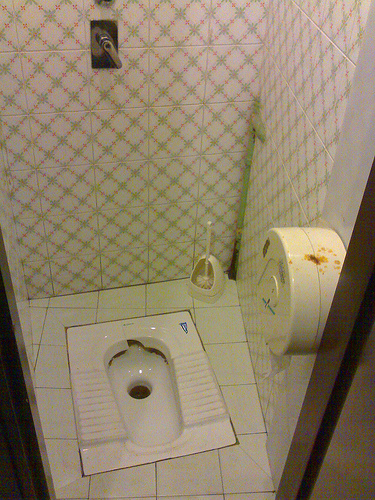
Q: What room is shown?
A: It is a bathroom.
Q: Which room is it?
A: It is a bathroom.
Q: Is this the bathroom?
A: Yes, it is the bathroom.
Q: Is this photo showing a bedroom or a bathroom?
A: It is showing a bathroom.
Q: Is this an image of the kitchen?
A: No, the picture is showing the bathroom.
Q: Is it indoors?
A: Yes, it is indoors.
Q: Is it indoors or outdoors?
A: It is indoors.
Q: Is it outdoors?
A: No, it is indoors.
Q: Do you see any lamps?
A: No, there are no lamps.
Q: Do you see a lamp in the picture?
A: No, there are no lamps.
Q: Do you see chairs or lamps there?
A: No, there are no lamps or chairs.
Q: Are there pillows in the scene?
A: No, there are no pillows.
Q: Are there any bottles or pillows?
A: No, there are no pillows or bottles.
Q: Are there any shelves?
A: No, there are no shelves.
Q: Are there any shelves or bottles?
A: No, there are no shelves or bottles.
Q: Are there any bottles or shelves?
A: No, there are no shelves or bottles.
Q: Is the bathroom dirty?
A: Yes, the bathroom is dirty.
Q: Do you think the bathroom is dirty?
A: Yes, the bathroom is dirty.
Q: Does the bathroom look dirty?
A: Yes, the bathroom is dirty.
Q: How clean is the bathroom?
A: The bathroom is dirty.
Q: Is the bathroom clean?
A: No, the bathroom is dirty.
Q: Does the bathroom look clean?
A: No, the bathroom is dirty.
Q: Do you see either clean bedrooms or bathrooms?
A: No, there is a bathroom but it is dirty.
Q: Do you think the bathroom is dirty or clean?
A: The bathroom is dirty.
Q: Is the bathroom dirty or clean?
A: The bathroom is dirty.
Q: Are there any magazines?
A: No, there are no magazines.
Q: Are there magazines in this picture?
A: No, there are no magazines.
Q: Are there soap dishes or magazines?
A: No, there are no magazines or soap dishes.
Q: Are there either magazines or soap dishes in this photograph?
A: No, there are no magazines or soap dishes.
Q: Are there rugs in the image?
A: No, there are no rugs.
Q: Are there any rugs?
A: No, there are no rugs.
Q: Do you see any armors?
A: No, there are no armors.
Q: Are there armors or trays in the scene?
A: No, there are no armors or trays.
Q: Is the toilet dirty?
A: Yes, the toilet is dirty.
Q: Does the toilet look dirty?
A: Yes, the toilet is dirty.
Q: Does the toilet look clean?
A: No, the toilet is dirty.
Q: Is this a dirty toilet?
A: Yes, this is a dirty toilet.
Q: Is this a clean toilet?
A: No, this is a dirty toilet.